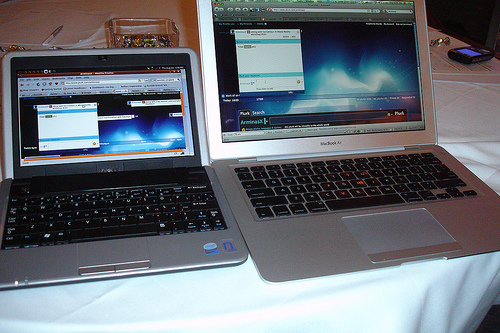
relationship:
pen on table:
[25, 49, 80, 50] [7, 119, 494, 333]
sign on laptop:
[315, 129, 349, 157] [5, 100, 255, 329]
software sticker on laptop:
[197, 240, 222, 256] [2, 83, 282, 273]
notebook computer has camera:
[4, 47, 251, 299] [74, 100, 80, 106]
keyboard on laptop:
[5, 176, 225, 244] [9, 114, 249, 327]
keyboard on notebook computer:
[5, 176, 225, 244] [4, 47, 251, 299]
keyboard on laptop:
[5, 176, 225, 244] [1, 115, 229, 173]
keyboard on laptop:
[5, 185, 225, 261] [9, 70, 241, 306]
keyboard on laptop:
[7, 170, 234, 258] [6, 122, 246, 303]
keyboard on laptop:
[1, 110, 241, 292] [5, 178, 231, 240]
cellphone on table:
[6, 178, 224, 258] [25, 112, 482, 322]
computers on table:
[11, 112, 477, 278] [17, 56, 493, 330]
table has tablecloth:
[15, 83, 495, 333] [39, 110, 499, 333]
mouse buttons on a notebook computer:
[342, 196, 456, 265] [195, 3, 498, 284]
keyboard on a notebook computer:
[226, 142, 478, 236] [195, 3, 498, 284]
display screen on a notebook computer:
[215, 7, 427, 147] [195, 3, 498, 284]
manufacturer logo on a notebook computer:
[310, 136, 350, 154] [195, 3, 498, 284]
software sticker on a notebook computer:
[197, 240, 222, 256] [4, 47, 251, 299]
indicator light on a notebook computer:
[12, 280, 21, 289] [4, 47, 251, 299]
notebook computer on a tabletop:
[4, 47, 251, 299] [6, 2, 498, 331]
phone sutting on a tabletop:
[450, 50, 490, 76] [6, 2, 498, 331]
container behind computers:
[102, 0, 187, 50] [4, 5, 498, 283]